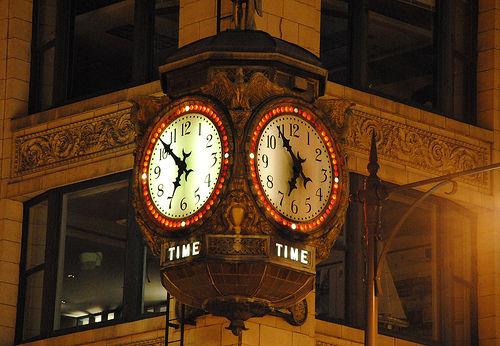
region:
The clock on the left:
[138, 93, 231, 233]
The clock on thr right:
[243, 93, 345, 233]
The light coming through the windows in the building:
[65, 299, 120, 326]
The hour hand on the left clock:
[170, 144, 191, 199]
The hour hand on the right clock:
[285, 151, 307, 199]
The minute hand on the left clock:
[155, 133, 192, 180]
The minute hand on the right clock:
[274, 123, 313, 189]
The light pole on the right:
[342, 119, 499, 344]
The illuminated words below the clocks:
[167, 238, 314, 268]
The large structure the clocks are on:
[119, 25, 359, 338]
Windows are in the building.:
[8, 162, 193, 343]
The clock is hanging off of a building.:
[122, 30, 367, 330]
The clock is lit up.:
[128, 63, 353, 285]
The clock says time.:
[159, 230, 317, 292]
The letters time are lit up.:
[149, 225, 327, 297]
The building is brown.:
[2, 5, 491, 340]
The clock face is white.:
[129, 97, 346, 237]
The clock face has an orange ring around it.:
[124, 89, 346, 241]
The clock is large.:
[117, 26, 354, 326]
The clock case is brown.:
[122, 33, 345, 332]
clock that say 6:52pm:
[129, 99, 246, 241]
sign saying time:
[141, 225, 233, 270]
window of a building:
[29, 184, 197, 343]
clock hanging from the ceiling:
[93, 27, 378, 344]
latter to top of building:
[157, 292, 189, 343]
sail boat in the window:
[371, 232, 417, 342]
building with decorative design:
[10, 125, 150, 175]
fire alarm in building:
[74, 240, 123, 284]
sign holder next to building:
[342, 135, 480, 331]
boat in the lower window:
[363, 192, 448, 338]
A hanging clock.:
[137, 97, 347, 245]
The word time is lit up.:
[151, 223, 325, 279]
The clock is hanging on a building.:
[117, 20, 359, 331]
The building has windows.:
[13, 159, 184, 332]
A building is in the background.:
[2, 0, 497, 342]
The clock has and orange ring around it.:
[134, 86, 352, 240]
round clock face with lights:
[245, 92, 355, 239]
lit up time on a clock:
[268, 240, 315, 270]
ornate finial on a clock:
[205, 296, 270, 336]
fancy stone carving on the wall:
[350, 105, 495, 190]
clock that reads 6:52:
[130, 91, 240, 231]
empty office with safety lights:
[55, 270, 130, 330]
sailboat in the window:
[372, 236, 419, 331]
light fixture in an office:
[75, 240, 107, 271]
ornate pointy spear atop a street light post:
[355, 122, 415, 324]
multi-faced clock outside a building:
[124, 22, 376, 344]